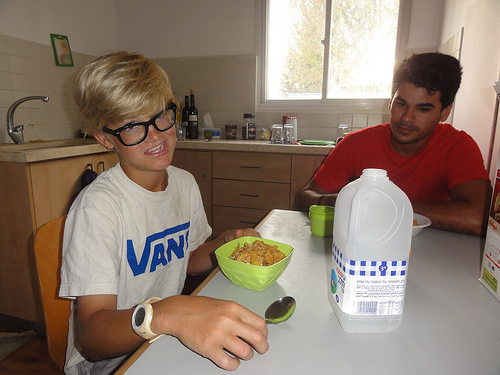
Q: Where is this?
A: This is at the kitchen.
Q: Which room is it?
A: It is a kitchen.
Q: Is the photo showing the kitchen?
A: Yes, it is showing the kitchen.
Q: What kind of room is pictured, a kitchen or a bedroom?
A: It is a kitchen.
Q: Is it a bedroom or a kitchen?
A: It is a kitchen.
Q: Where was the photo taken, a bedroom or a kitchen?
A: It was taken at a kitchen.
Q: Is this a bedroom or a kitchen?
A: It is a kitchen.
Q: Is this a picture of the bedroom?
A: No, the picture is showing the kitchen.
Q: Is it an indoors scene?
A: Yes, it is indoors.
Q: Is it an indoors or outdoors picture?
A: It is indoors.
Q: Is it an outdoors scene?
A: No, it is indoors.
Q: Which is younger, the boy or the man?
A: The boy is younger than the man.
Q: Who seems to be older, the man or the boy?
A: The man is older than the boy.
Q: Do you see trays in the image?
A: No, there are no trays.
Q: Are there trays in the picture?
A: No, there are no trays.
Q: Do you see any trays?
A: No, there are no trays.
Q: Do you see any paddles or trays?
A: No, there are no trays or paddles.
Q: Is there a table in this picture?
A: Yes, there is a table.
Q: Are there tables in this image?
A: Yes, there is a table.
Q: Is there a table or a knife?
A: Yes, there is a table.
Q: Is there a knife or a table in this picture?
A: Yes, there is a table.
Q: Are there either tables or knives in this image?
A: Yes, there is a table.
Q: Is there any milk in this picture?
A: Yes, there is milk.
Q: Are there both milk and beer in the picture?
A: No, there is milk but no beer.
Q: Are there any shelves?
A: No, there are no shelves.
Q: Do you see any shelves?
A: No, there are no shelves.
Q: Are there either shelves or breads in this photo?
A: No, there are no shelves or breads.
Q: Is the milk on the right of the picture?
A: Yes, the milk is on the right of the image.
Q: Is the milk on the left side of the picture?
A: No, the milk is on the right of the image.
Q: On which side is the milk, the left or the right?
A: The milk is on the right of the image.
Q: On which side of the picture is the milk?
A: The milk is on the right of the image.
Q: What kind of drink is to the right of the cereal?
A: The drink is milk.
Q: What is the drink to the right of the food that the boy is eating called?
A: The drink is milk.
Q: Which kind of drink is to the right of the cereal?
A: The drink is milk.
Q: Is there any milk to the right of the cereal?
A: Yes, there is milk to the right of the cereal.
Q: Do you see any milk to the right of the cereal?
A: Yes, there is milk to the right of the cereal.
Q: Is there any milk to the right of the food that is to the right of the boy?
A: Yes, there is milk to the right of the cereal.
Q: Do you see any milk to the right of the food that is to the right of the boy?
A: Yes, there is milk to the right of the cereal.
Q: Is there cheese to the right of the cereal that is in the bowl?
A: No, there is milk to the right of the cereal.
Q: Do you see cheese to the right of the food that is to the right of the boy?
A: No, there is milk to the right of the cereal.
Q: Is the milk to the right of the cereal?
A: Yes, the milk is to the right of the cereal.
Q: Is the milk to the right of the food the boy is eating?
A: Yes, the milk is to the right of the cereal.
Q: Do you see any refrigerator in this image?
A: No, there are no refrigerators.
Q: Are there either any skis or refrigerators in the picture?
A: No, there are no refrigerators or skis.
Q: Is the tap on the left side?
A: Yes, the tap is on the left of the image.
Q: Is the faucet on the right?
A: No, the faucet is on the left of the image.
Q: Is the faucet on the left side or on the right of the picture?
A: The faucet is on the left of the image.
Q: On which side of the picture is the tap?
A: The tap is on the left of the image.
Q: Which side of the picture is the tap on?
A: The tap is on the left of the image.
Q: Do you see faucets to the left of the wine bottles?
A: Yes, there is a faucet to the left of the wine bottles.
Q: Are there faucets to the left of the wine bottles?
A: Yes, there is a faucet to the left of the wine bottles.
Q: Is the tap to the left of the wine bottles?
A: Yes, the tap is to the left of the wine bottles.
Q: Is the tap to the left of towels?
A: No, the tap is to the left of the wine bottles.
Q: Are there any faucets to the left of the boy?
A: Yes, there is a faucet to the left of the boy.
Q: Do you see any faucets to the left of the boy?
A: Yes, there is a faucet to the left of the boy.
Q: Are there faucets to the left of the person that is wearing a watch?
A: Yes, there is a faucet to the left of the boy.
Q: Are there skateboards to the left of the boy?
A: No, there is a faucet to the left of the boy.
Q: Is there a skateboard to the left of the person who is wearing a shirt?
A: No, there is a faucet to the left of the boy.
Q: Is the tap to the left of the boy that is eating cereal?
A: Yes, the tap is to the left of the boy.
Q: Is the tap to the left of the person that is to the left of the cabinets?
A: Yes, the tap is to the left of the boy.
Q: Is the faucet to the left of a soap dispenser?
A: No, the faucet is to the left of the boy.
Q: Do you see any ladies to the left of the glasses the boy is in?
A: No, there is a faucet to the left of the glasses.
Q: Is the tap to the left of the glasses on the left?
A: Yes, the tap is to the left of the glasses.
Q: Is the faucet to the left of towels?
A: No, the faucet is to the left of the glasses.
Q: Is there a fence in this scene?
A: No, there are no fences.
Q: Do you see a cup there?
A: Yes, there is a cup.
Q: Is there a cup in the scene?
A: Yes, there is a cup.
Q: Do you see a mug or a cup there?
A: Yes, there is a cup.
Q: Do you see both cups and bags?
A: No, there is a cup but no bags.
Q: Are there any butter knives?
A: No, there are no butter knives.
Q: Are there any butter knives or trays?
A: No, there are no butter knives or trays.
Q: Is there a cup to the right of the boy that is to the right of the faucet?
A: Yes, there is a cup to the right of the boy.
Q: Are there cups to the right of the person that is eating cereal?
A: Yes, there is a cup to the right of the boy.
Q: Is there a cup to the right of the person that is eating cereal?
A: Yes, there is a cup to the right of the boy.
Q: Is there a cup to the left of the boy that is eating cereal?
A: No, the cup is to the right of the boy.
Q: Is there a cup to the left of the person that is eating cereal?
A: No, the cup is to the right of the boy.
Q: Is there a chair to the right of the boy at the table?
A: No, there is a cup to the right of the boy.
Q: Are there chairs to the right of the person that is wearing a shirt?
A: No, there is a cup to the right of the boy.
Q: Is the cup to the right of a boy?
A: Yes, the cup is to the right of a boy.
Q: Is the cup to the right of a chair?
A: No, the cup is to the right of a boy.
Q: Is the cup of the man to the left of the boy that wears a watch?
A: No, the cup is to the right of the boy.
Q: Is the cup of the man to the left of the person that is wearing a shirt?
A: No, the cup is to the right of the boy.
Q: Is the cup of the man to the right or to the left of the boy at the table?
A: The cup is to the right of the boy.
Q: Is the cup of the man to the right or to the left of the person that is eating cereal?
A: The cup is to the right of the boy.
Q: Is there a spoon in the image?
A: Yes, there is a spoon.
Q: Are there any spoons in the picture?
A: Yes, there is a spoon.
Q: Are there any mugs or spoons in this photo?
A: Yes, there is a spoon.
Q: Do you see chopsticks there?
A: No, there are no chopsticks.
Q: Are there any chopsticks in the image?
A: No, there are no chopsticks.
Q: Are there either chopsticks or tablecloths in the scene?
A: No, there are no chopsticks or tablecloths.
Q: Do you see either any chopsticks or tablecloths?
A: No, there are no chopsticks or tablecloths.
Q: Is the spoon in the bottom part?
A: Yes, the spoon is in the bottom of the image.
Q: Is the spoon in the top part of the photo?
A: No, the spoon is in the bottom of the image.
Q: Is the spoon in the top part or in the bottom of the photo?
A: The spoon is in the bottom of the image.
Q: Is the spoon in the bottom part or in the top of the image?
A: The spoon is in the bottom of the image.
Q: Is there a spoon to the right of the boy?
A: Yes, there is a spoon to the right of the boy.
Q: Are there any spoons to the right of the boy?
A: Yes, there is a spoon to the right of the boy.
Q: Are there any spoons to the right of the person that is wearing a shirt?
A: Yes, there is a spoon to the right of the boy.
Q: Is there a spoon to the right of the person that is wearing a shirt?
A: Yes, there is a spoon to the right of the boy.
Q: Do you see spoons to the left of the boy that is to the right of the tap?
A: No, the spoon is to the right of the boy.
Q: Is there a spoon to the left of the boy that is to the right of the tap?
A: No, the spoon is to the right of the boy.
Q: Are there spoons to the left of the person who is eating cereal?
A: No, the spoon is to the right of the boy.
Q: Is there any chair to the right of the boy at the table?
A: No, there is a spoon to the right of the boy.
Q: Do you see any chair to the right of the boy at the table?
A: No, there is a spoon to the right of the boy.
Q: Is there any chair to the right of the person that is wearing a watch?
A: No, there is a spoon to the right of the boy.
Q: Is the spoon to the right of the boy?
A: Yes, the spoon is to the right of the boy.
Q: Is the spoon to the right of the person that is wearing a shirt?
A: Yes, the spoon is to the right of the boy.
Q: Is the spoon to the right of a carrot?
A: No, the spoon is to the right of the boy.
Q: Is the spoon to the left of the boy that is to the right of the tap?
A: No, the spoon is to the right of the boy.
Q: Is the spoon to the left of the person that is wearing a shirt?
A: No, the spoon is to the right of the boy.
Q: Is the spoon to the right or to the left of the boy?
A: The spoon is to the right of the boy.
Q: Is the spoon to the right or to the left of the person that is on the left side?
A: The spoon is to the right of the boy.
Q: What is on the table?
A: The spoon is on the table.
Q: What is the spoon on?
A: The spoon is on the table.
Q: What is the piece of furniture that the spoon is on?
A: The piece of furniture is a table.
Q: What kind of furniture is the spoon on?
A: The spoon is on the table.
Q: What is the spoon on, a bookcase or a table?
A: The spoon is on a table.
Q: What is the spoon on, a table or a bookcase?
A: The spoon is on a table.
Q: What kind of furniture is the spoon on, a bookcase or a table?
A: The spoon is on a table.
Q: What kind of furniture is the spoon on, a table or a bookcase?
A: The spoon is on a table.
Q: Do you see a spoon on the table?
A: Yes, there is a spoon on the table.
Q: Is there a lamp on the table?
A: No, there is a spoon on the table.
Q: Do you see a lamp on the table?
A: No, there is a spoon on the table.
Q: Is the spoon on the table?
A: Yes, the spoon is on the table.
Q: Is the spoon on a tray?
A: No, the spoon is on the table.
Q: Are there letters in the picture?
A: Yes, there are letters.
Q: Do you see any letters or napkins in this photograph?
A: Yes, there are letters.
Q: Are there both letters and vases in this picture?
A: No, there are letters but no vases.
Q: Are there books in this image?
A: No, there are no books.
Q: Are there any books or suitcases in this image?
A: No, there are no books or suitcases.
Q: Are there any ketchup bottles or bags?
A: No, there are no bags or ketchup bottles.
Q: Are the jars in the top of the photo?
A: Yes, the jars are in the top of the image.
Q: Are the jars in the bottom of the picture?
A: No, the jars are in the top of the image.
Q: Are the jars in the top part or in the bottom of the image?
A: The jars are in the top of the image.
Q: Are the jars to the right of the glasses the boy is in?
A: Yes, the jars are to the right of the glasses.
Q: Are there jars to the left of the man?
A: Yes, there are jars to the left of the man.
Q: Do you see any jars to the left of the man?
A: Yes, there are jars to the left of the man.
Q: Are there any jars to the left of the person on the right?
A: Yes, there are jars to the left of the man.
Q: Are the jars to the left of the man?
A: Yes, the jars are to the left of the man.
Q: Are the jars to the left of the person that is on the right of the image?
A: Yes, the jars are to the left of the man.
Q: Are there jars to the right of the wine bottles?
A: Yes, there are jars to the right of the wine bottles.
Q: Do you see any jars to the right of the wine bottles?
A: Yes, there are jars to the right of the wine bottles.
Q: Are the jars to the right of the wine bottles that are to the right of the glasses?
A: Yes, the jars are to the right of the wine bottles.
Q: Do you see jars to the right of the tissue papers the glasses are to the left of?
A: Yes, there are jars to the right of the tissue papers.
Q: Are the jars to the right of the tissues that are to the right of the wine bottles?
A: Yes, the jars are to the right of the tissues.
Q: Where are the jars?
A: The jars are in the kitchen.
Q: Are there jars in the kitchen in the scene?
A: Yes, there are jars in the kitchen.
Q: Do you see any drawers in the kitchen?
A: No, there are jars in the kitchen.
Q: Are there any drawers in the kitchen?
A: No, there are jars in the kitchen.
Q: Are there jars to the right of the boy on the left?
A: Yes, there are jars to the right of the boy.